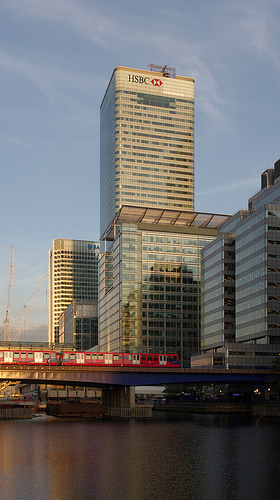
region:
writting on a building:
[125, 74, 165, 85]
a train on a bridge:
[0, 350, 180, 369]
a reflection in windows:
[124, 258, 199, 350]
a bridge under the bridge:
[46, 392, 100, 419]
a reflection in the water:
[14, 416, 216, 490]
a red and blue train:
[2, 352, 177, 366]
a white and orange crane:
[3, 240, 50, 343]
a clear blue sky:
[11, 3, 279, 63]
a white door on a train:
[105, 352, 112, 362]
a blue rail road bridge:
[5, 366, 275, 380]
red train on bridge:
[11, 338, 188, 377]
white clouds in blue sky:
[22, 21, 64, 65]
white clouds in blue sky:
[44, 105, 83, 150]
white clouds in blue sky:
[32, 124, 50, 157]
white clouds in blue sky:
[12, 146, 56, 175]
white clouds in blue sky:
[17, 191, 67, 217]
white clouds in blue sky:
[80, 13, 141, 47]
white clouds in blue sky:
[191, 31, 240, 53]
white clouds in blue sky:
[199, 40, 246, 84]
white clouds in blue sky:
[208, 86, 260, 132]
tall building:
[122, 70, 202, 347]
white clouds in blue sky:
[29, 139, 96, 186]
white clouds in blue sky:
[14, 69, 58, 118]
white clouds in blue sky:
[4, 169, 28, 188]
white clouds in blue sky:
[16, 205, 34, 232]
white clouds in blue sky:
[151, 20, 177, 50]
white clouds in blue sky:
[191, 10, 243, 35]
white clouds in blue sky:
[216, 10, 246, 61]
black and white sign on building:
[119, 69, 168, 95]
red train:
[18, 347, 178, 376]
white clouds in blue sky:
[12, 33, 36, 63]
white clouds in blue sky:
[8, 106, 54, 158]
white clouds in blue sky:
[23, 187, 55, 207]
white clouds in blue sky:
[9, 282, 32, 302]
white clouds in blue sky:
[38, 25, 74, 51]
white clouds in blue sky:
[180, 19, 225, 37]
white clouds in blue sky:
[212, 42, 256, 142]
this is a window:
[139, 354, 147, 361]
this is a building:
[38, 238, 104, 350]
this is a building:
[198, 160, 278, 370]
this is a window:
[10, 348, 20, 358]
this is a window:
[18, 350, 24, 360]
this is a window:
[38, 348, 48, 362]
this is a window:
[137, 351, 147, 362]